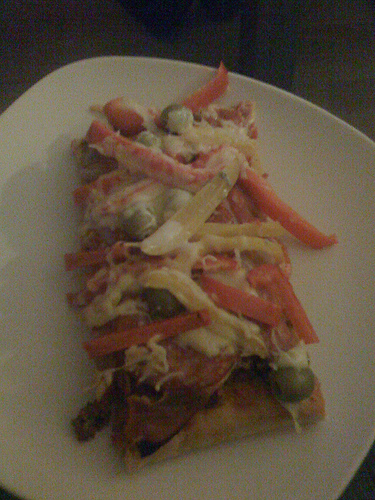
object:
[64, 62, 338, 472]
food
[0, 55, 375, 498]
plate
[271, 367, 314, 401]
pea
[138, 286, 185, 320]
pea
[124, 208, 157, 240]
pea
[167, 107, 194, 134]
pea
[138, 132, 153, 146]
pea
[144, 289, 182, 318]
pea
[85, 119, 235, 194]
pepper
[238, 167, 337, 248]
pepper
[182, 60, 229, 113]
pepper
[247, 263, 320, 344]
pepper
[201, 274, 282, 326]
pepper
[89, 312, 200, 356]
pepper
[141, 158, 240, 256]
pepper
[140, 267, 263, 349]
pepper